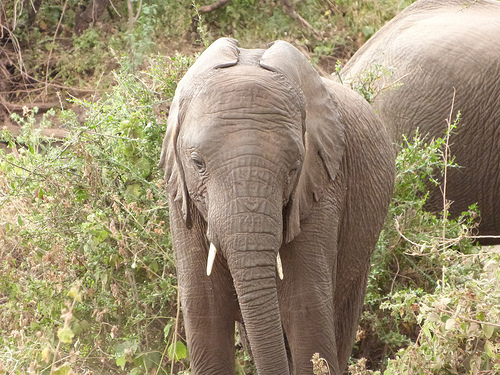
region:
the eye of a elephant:
[174, 140, 235, 195]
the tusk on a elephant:
[196, 230, 242, 283]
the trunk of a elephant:
[179, 240, 339, 364]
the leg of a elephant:
[153, 268, 262, 371]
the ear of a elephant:
[146, 71, 246, 210]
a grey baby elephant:
[133, 79, 471, 329]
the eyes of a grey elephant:
[171, 133, 341, 191]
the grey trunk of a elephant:
[227, 248, 336, 358]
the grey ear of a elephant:
[131, 103, 226, 220]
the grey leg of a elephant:
[150, 226, 273, 363]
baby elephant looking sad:
[150, 34, 377, 373]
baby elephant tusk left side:
[203, 238, 215, 283]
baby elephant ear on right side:
[290, 38, 342, 245]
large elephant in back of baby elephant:
[326, 3, 497, 243]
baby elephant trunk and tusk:
[208, 179, 300, 372]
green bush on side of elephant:
[394, 131, 499, 372]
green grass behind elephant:
[3, 32, 163, 373]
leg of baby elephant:
[178, 265, 238, 374]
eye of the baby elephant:
[186, 154, 207, 176]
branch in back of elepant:
[1, 93, 89, 114]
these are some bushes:
[23, 16, 143, 303]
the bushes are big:
[23, 93, 169, 373]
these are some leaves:
[92, 115, 140, 155]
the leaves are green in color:
[95, 122, 150, 180]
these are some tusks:
[201, 239, 288, 284]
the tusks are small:
[203, 235, 294, 293]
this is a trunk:
[224, 259, 301, 374]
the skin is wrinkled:
[211, 94, 272, 134]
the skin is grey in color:
[350, 137, 371, 210]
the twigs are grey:
[25, 77, 47, 89]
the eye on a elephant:
[140, 145, 227, 198]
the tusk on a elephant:
[171, 194, 336, 296]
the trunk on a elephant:
[236, 255, 313, 369]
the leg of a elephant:
[173, 208, 317, 362]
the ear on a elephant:
[133, 56, 254, 225]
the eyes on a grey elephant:
[165, 126, 347, 203]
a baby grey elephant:
[143, 43, 484, 365]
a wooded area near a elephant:
[31, 5, 286, 296]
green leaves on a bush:
[50, 0, 247, 195]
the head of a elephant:
[142, 53, 371, 281]